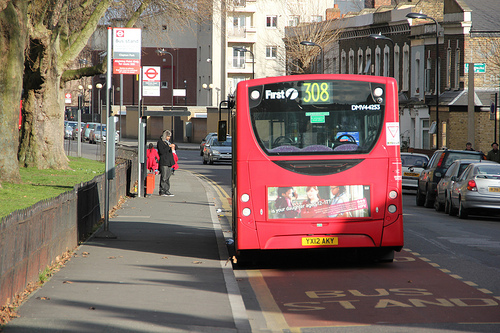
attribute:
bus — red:
[227, 80, 399, 256]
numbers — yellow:
[302, 82, 330, 104]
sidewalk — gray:
[89, 156, 249, 328]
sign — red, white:
[140, 66, 162, 96]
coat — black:
[157, 137, 173, 163]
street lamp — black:
[406, 13, 439, 149]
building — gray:
[196, 8, 301, 105]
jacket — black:
[158, 143, 178, 164]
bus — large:
[217, 63, 415, 275]